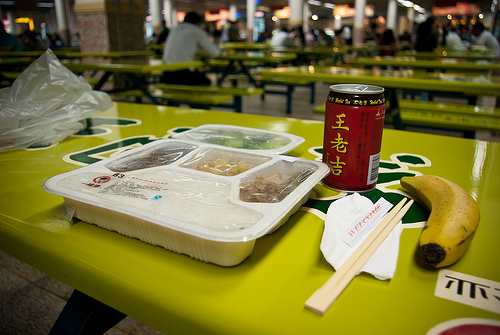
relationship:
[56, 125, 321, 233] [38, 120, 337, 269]
dinner in container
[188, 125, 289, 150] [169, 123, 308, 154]
side dish in tray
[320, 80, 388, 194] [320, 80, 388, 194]
beverage in beverage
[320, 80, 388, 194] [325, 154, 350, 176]
beverage has chinese characters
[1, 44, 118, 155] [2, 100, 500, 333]
bag on cafeteria table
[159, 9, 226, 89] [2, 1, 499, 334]
man in food court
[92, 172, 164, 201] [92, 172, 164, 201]
heating instructions has heating instructions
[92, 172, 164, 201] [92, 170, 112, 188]
heating instructions has warning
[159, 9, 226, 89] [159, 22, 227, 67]
man wears shirt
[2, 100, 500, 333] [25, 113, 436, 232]
cafeteria table has green writing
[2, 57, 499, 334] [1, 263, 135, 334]
floor has tile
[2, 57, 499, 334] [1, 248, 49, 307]
floor has tile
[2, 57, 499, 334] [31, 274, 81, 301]
floor has tile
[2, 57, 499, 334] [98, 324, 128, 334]
floor has tile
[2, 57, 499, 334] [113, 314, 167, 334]
floor has tile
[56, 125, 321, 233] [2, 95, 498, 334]
dinner on cafeteria table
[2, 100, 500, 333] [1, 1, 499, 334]
cafeteria table in cafeteria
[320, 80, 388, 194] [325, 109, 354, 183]
beverage has chinese characters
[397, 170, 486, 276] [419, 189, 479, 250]
banana has brown specks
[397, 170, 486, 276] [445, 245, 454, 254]
banana has brown speck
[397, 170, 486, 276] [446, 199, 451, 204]
banana has brown speck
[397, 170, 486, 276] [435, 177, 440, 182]
banana has brown speck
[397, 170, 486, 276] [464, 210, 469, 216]
banana has brown speck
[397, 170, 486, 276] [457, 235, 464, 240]
banana has brown speck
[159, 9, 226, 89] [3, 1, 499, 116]
man in background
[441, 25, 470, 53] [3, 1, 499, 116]
man in background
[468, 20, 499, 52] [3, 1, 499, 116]
man in background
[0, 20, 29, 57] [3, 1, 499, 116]
man in background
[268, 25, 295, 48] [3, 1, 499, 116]
man in background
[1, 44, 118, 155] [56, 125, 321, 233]
bag beside dinner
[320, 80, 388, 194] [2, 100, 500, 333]
beverage on cafeteria table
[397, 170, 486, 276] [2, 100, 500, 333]
banana on cafeteria table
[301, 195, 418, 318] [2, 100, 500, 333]
chopsticks on cafeteria table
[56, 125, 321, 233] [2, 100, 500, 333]
dinner on cafeteria table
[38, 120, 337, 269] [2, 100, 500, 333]
container on cafeteria table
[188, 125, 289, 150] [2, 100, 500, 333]
side dish on cafeteria table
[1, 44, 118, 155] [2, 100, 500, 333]
plastic on cafeteria table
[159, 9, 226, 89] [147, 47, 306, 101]
man at table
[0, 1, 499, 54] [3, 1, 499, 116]
group in background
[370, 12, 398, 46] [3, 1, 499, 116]
person in background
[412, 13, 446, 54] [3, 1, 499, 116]
person in background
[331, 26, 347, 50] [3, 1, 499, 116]
person in background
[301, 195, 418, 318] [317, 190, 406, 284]
chopsticks on napkin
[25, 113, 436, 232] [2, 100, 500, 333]
green writing on cafeteria table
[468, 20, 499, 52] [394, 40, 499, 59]
man at tables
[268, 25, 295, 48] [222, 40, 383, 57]
man at tables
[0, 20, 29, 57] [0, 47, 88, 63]
man at tables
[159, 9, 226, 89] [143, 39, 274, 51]
man at tables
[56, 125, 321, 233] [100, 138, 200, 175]
dinner in compartment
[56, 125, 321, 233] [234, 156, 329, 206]
dinner in compartment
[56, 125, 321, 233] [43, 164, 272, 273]
dinner in compartment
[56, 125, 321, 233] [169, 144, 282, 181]
dinner in compartment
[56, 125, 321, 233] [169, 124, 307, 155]
dinner in compartment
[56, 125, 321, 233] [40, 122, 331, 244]
dinner covered by plastic